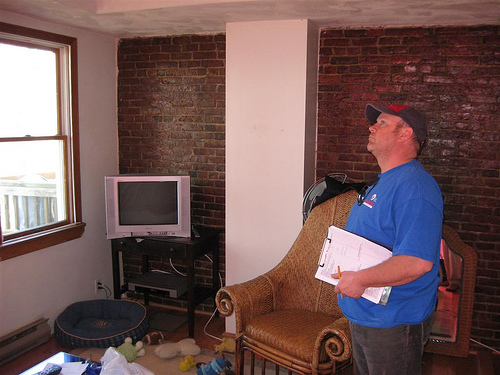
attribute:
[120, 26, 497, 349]
wall — brick, red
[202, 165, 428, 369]
chair — rust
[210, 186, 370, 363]
chair — brown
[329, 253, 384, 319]
hand — man's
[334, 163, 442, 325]
tshirt — blue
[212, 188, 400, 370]
chair — brown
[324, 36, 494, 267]
wall — brick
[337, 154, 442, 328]
shirt — blue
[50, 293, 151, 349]
bed — pet's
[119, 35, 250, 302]
wall — brick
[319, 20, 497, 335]
wall — brick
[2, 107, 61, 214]
window — glass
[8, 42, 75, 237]
windows — closed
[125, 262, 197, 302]
unit — VCR